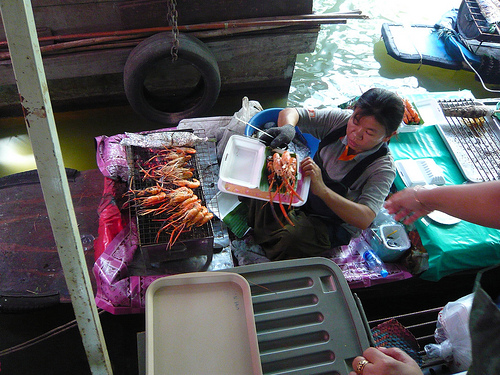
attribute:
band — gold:
[356, 358, 369, 370]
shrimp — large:
[120, 141, 215, 251]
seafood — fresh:
[113, 124, 235, 289]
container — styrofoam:
[215, 130, 312, 207]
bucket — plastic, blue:
[226, 98, 321, 188]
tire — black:
[119, 23, 221, 120]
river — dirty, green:
[5, 0, 496, 164]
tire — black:
[117, 35, 219, 127]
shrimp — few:
[134, 140, 216, 238]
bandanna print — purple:
[94, 257, 138, 308]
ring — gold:
[355, 358, 367, 372]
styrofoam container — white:
[390, 153, 448, 190]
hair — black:
[348, 86, 403, 139]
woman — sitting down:
[223, 87, 407, 275]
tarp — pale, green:
[363, 117, 499, 274]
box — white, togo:
[397, 159, 446, 182]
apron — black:
[248, 120, 386, 261]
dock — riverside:
[28, 87, 469, 370]